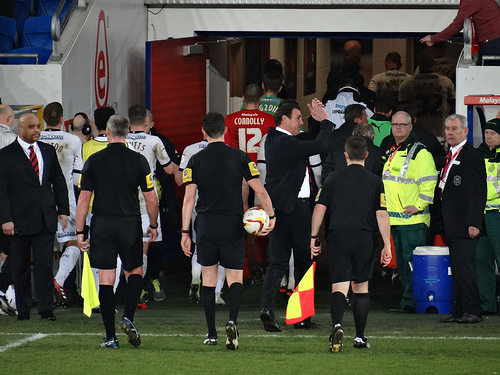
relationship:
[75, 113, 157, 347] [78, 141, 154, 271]
man wears uniform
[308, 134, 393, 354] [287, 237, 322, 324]
man holding flag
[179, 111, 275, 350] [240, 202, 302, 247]
guy holding soccer ball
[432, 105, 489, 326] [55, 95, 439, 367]
man watching players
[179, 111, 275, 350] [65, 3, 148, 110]
guy walking into tunnel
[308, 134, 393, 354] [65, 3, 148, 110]
man walking into tunnel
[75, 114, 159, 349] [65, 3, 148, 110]
man walking into tunnel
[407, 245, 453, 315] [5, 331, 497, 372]
cooler on field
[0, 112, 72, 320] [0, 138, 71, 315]
bald guy in suit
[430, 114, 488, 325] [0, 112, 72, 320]
man in bald guy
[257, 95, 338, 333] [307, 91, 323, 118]
man clapping hand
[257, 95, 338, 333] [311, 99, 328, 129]
man clapping hand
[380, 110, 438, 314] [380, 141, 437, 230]
guy in jacket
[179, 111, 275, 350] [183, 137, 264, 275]
guy wearing uniform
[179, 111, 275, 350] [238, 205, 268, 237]
guy holding ball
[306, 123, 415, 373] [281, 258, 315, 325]
man holding flag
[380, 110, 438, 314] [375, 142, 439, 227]
guy wearing shirt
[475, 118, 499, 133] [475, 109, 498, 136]
man wearing toboggan hat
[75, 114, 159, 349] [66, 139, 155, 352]
man wearing uniform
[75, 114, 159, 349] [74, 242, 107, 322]
man holding towel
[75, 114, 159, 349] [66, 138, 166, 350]
man wearing uniform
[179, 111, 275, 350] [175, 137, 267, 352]
guy wearing uniform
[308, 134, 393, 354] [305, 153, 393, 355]
man wearing uniform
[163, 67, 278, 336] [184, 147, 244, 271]
man wearing soccer uniform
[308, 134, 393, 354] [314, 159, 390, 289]
man wearing uniform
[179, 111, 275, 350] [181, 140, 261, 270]
guy wearing soccer uniform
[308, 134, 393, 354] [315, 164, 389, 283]
man wearing uniform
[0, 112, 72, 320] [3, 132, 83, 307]
bald guy wearing suit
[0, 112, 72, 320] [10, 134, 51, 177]
bald guy has tie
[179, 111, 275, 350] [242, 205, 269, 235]
guy carrying ball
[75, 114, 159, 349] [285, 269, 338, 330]
man carrying flag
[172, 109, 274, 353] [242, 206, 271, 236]
guy carrying ball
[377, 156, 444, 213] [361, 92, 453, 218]
top on guy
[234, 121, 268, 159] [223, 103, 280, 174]
number on uniform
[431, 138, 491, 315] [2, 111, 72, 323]
suit on bald guy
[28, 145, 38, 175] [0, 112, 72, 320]
tie on bald guy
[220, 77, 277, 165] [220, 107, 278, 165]
man wear red jersey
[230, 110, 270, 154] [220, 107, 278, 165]
white lettering on red jersey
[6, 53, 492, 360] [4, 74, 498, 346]
crowd in game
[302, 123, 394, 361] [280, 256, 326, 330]
boy carry flag